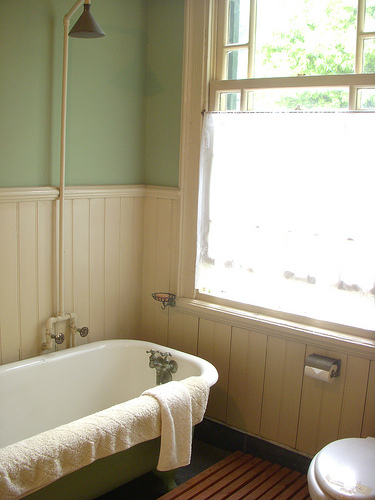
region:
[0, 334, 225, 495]
white and olive green bath tub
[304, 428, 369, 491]
white toilet in a bathroom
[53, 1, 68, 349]
large white pipeline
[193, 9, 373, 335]
big white window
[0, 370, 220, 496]
white bath towels in the tub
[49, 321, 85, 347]
two grey wrench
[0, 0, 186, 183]
light green wall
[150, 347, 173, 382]
one grey wrench in the tub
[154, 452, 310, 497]
brown bath mat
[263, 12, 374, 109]
green leaves outside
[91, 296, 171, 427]
a tub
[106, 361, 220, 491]
a tub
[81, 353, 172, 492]
a tub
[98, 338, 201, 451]
a tub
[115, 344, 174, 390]
silver old bath tub faucets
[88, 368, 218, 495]
white towel over bathtub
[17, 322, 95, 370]
two handles of hot and cold water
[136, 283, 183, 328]
an old style soap dish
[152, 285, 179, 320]
pink soap in a dish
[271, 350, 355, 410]
a roll of white toilet paper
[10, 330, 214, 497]
a white and green bath tub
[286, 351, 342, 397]
silver toilet paper roll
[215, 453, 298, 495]
brown wooden bath tub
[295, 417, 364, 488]
white toilet and seat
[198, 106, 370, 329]
window with bright sunshine shining through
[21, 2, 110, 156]
shower head with green wall behind it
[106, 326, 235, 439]
towels hanging from edge of bathtub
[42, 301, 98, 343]
shower knobs connected to pipe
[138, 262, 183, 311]
soap dish connected to window sill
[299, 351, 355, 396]
toliet paper on the toilet roll holder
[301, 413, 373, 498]
toilet next to paneled wall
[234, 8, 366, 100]
tree outside bright window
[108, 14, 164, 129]
shadow of the shower head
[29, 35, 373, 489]
well designed and clean bathroom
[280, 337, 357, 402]
toilet paper holder on wall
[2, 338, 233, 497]
old-fashioned green bathtub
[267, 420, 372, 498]
toilet seat cover is closed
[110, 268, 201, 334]
soap holder mounted on wall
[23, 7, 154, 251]
rainfall-type of showerhead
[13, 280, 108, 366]
hot and cold water faucets on wall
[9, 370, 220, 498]
two towels draped over side of tub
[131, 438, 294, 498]
wood pallet on floor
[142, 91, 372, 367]
large window in bathroom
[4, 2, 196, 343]
sage green walls and light paneling